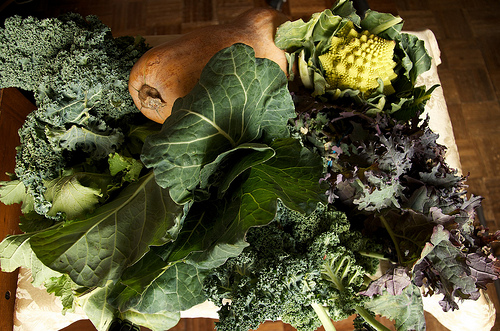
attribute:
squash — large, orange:
[128, 8, 302, 119]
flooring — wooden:
[363, 0, 498, 252]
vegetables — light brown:
[18, 21, 467, 324]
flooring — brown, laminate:
[425, 7, 497, 194]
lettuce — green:
[145, 57, 330, 239]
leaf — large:
[135, 40, 320, 272]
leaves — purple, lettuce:
[290, 69, 487, 329]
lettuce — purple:
[311, 108, 498, 318]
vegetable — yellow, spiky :
[312, 19, 404, 91]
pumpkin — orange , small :
[127, 0, 304, 127]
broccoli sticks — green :
[1, 15, 151, 217]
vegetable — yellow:
[314, 26, 405, 97]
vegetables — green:
[4, 16, 204, 291]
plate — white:
[411, 77, 441, 154]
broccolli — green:
[2, 13, 137, 216]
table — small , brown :
[444, 56, 496, 156]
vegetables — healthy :
[38, 71, 459, 282]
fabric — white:
[11, 29, 492, 329]